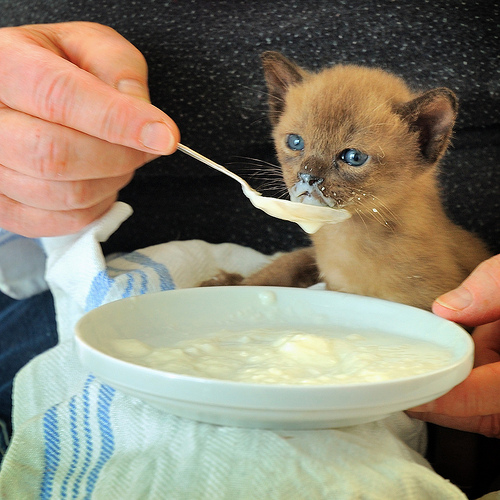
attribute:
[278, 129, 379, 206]
face — messy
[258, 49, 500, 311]
kitten — eating, brown, small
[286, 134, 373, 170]
eyes — blue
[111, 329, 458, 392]
food — white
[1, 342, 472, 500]
towel — white, blue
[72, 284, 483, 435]
bowl — white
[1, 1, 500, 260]
shirt — gray, spotted